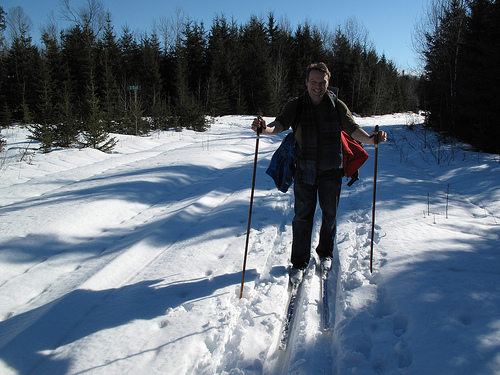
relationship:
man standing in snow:
[252, 61, 389, 278] [1, 111, 499, 375]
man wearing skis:
[250, 61, 388, 285] [277, 275, 339, 350]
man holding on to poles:
[250, 61, 388, 285] [240, 131, 382, 298]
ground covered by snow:
[1, 107, 499, 373] [1, 111, 499, 375]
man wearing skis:
[252, 61, 389, 278] [277, 275, 339, 350]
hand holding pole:
[371, 128, 389, 149] [370, 122, 380, 277]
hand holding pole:
[251, 116, 267, 136] [237, 109, 264, 297]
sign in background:
[126, 85, 144, 92] [3, 1, 500, 167]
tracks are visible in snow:
[196, 182, 414, 375] [1, 111, 499, 375]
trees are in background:
[2, 0, 499, 158] [3, 1, 500, 167]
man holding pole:
[252, 61, 389, 278] [370, 122, 380, 277]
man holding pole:
[252, 61, 389, 278] [237, 109, 264, 297]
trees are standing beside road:
[2, 0, 499, 158] [4, 56, 430, 375]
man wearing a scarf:
[252, 61, 389, 278] [301, 89, 337, 188]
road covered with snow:
[4, 56, 430, 375] [1, 111, 499, 375]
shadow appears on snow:
[0, 268, 264, 373] [1, 111, 499, 375]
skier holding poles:
[252, 61, 390, 284] [240, 131, 382, 298]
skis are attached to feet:
[277, 275, 339, 350] [288, 255, 331, 285]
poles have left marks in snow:
[240, 131, 382, 298] [1, 111, 499, 375]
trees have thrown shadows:
[2, 0, 499, 158] [0, 123, 499, 371]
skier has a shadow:
[252, 61, 390, 284] [0, 268, 264, 373]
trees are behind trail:
[2, 0, 499, 158] [8, 113, 420, 375]